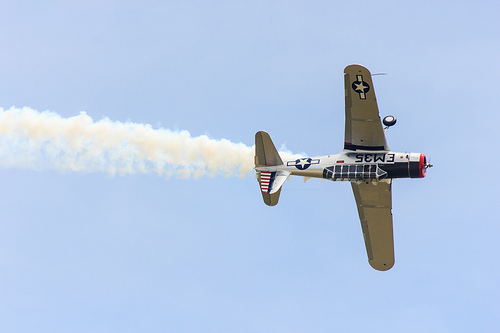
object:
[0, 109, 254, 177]
exhaust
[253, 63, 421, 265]
airplane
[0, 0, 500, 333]
air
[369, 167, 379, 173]
window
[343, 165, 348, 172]
window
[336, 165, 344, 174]
window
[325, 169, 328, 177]
window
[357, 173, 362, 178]
window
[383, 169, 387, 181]
cockpit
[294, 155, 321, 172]
star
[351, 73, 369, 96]
star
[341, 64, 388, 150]
wing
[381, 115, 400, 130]
wheel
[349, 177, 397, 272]
wing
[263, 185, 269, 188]
stripe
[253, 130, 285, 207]
tail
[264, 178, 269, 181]
stripe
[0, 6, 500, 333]
sky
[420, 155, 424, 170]
paint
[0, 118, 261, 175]
smoke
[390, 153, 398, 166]
letter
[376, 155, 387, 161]
letter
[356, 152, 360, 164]
number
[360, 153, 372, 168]
number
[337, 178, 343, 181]
metal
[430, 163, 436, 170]
nose